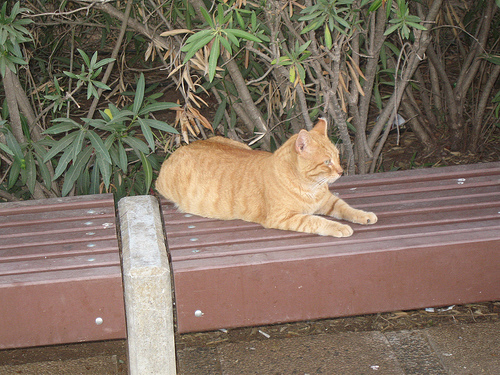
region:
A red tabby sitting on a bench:
[146, 110, 376, 235]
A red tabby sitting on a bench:
[150, 106, 380, 248]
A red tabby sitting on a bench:
[150, 111, 380, 241]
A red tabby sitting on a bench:
[146, 110, 378, 245]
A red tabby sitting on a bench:
[147, 111, 374, 241]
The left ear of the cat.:
[294, 130, 309, 152]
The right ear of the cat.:
[317, 116, 329, 134]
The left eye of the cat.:
[322, 158, 329, 167]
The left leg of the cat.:
[296, 216, 344, 238]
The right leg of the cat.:
[326, 195, 355, 217]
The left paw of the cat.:
[334, 226, 352, 238]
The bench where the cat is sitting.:
[157, 152, 497, 319]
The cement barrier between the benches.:
[118, 193, 185, 373]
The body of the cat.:
[164, 135, 269, 216]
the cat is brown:
[171, 133, 371, 240]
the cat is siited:
[171, 135, 365, 241]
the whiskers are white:
[306, 172, 330, 197]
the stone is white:
[118, 192, 173, 366]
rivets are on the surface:
[192, 307, 204, 319]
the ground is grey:
[302, 342, 391, 369]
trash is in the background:
[376, 109, 407, 129]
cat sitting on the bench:
[161, 111, 383, 246]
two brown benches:
[3, 158, 496, 360]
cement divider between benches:
[120, 191, 180, 372]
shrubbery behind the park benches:
[5, 6, 498, 163]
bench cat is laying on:
[162, 171, 499, 319]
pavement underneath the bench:
[0, 321, 498, 374]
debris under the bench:
[252, 296, 490, 374]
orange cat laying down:
[153, 121, 380, 241]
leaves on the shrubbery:
[1, 3, 440, 187]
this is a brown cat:
[169, 118, 383, 253]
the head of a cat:
[289, 110, 349, 177]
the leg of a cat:
[336, 200, 381, 225]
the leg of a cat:
[320, 211, 352, 239]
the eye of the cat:
[318, 152, 335, 169]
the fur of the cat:
[231, 156, 262, 181]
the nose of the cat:
[333, 160, 347, 182]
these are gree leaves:
[73, 110, 150, 164]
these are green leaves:
[193, 2, 246, 59]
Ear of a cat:
[293, 128, 309, 158]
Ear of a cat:
[292, 129, 311, 152]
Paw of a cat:
[328, 220, 353, 244]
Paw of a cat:
[358, 208, 383, 229]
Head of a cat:
[288, 118, 347, 194]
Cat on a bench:
[156, 124, 387, 250]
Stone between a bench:
[108, 189, 190, 373]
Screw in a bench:
[193, 307, 205, 322]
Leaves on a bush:
[61, 117, 145, 187]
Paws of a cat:
[322, 219, 354, 244]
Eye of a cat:
[319, 154, 334, 173]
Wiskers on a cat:
[306, 176, 332, 190]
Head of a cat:
[279, 124, 350, 189]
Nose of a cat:
[331, 167, 348, 185]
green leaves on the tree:
[195, 23, 224, 61]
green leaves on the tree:
[58, 151, 112, 178]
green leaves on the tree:
[122, 126, 149, 174]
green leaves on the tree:
[89, 96, 202, 173]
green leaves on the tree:
[304, 100, 336, 111]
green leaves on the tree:
[317, 3, 349, 45]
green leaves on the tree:
[60, 51, 124, 104]